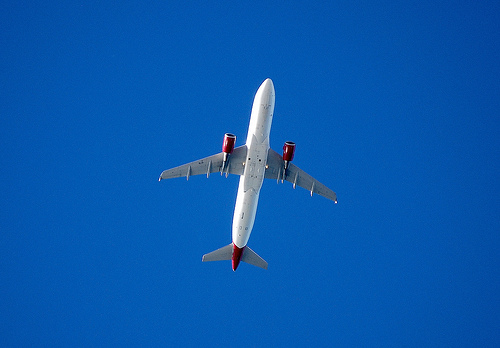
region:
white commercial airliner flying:
[197, 59, 316, 298]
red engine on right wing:
[215, 128, 235, 175]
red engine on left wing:
[275, 140, 298, 177]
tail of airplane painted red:
[211, 232, 271, 275]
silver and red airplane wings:
[161, 131, 340, 215]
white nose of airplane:
[250, 74, 277, 121]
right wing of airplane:
[162, 129, 251, 186]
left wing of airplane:
[276, 141, 340, 210]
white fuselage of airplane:
[253, 80, 275, 212]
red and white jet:
[190, 44, 295, 296]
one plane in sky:
[175, 15, 336, 274]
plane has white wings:
[162, 149, 338, 187]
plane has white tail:
[203, 236, 288, 272]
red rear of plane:
[227, 238, 244, 269]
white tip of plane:
[253, 59, 274, 93]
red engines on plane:
[217, 115, 302, 170]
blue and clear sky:
[79, 38, 199, 139]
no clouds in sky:
[77, 45, 192, 133]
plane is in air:
[180, 73, 311, 272]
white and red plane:
[168, 98, 308, 269]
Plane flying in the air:
[159, 76, 340, 274]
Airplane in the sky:
[157, 74, 339, 273]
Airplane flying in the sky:
[157, 70, 341, 273]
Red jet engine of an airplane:
[219, 128, 240, 154]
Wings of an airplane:
[160, 140, 340, 206]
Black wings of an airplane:
[195, 238, 273, 271]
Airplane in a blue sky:
[154, 75, 338, 270]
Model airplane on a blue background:
[152, 75, 340, 274]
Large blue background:
[2, 0, 499, 346]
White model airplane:
[153, 76, 336, 276]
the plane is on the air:
[159, 72, 343, 274]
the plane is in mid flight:
[156, 76, 343, 274]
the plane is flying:
[161, 74, 346, 271]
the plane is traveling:
[163, 76, 343, 273]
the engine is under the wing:
[221, 134, 236, 174]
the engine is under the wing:
[280, 140, 295, 182]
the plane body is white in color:
[226, 77, 278, 252]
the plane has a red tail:
[233, 236, 245, 271]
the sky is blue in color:
[1, 2, 498, 347]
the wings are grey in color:
[162, 136, 347, 211]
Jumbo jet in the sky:
[139, 37, 354, 283]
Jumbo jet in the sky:
[156, 143, 328, 302]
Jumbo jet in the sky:
[188, 71, 332, 221]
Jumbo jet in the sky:
[200, 196, 292, 292]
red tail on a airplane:
[214, 238, 260, 283]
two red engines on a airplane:
[200, 130, 307, 187]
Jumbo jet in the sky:
[130, 41, 357, 303]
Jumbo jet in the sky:
[133, 67, 359, 284]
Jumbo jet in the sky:
[150, 80, 348, 278]